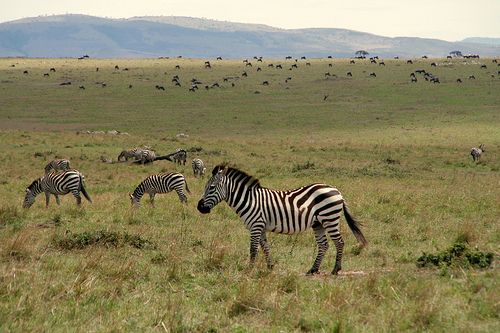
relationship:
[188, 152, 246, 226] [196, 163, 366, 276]
head of zebra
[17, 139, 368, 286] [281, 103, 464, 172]
several zebra in grass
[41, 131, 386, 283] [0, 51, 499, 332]
animals on a field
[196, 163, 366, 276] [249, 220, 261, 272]
zebra front leg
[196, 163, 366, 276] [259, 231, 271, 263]
zebra front leg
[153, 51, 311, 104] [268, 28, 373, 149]
animals on a hillside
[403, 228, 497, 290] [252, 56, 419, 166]
bush in a field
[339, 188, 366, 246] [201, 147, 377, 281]
tail on a zebra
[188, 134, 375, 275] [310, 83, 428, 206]
zebra eating in field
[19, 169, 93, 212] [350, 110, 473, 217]
animals eating in field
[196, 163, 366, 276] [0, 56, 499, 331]
zebra eating in field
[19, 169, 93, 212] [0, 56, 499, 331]
animals eating in field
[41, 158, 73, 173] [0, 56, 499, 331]
zebra eating in field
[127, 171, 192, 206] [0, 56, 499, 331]
zebra eating in field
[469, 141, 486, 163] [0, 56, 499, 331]
zebra eating in field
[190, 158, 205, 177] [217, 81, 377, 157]
zebra eating in field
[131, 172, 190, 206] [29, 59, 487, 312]
zebra walking in field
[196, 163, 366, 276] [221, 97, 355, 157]
zebra in a field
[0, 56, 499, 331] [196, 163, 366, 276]
field of zebra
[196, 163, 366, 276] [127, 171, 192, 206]
zebra of zebra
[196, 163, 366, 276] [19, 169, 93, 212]
zebra of animals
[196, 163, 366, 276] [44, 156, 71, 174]
zebra of zebra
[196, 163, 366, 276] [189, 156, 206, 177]
zebra of zebra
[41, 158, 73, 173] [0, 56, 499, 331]
zebra in field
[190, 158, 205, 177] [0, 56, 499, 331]
zebra in field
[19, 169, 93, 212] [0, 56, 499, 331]
animals in field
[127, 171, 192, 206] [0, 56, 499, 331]
zebra in field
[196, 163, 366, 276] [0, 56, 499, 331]
zebra in field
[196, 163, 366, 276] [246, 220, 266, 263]
zebra has leg